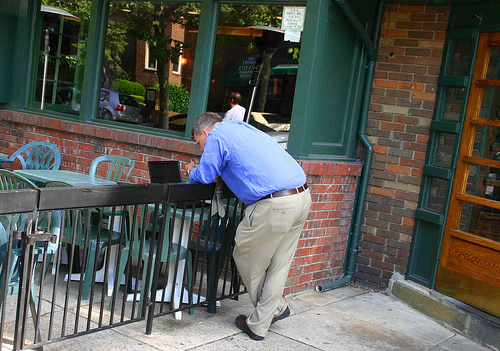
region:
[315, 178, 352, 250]
a brick wall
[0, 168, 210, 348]
a black wood fence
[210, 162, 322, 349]
a man wearing slacks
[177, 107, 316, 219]
a long sleeved blue shirt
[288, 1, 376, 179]
a green wall of the building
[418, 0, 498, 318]
a wooden door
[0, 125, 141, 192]
green chairs and table outside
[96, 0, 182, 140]
reflection in the glass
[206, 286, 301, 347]
brown shoes on a man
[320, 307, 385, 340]
cement on the ground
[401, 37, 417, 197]
brick exposed wall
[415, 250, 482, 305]
gold bottom portion of door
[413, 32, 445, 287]
green colored small window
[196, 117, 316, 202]
baby blue dress shirt on man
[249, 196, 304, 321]
tan khaki dress pants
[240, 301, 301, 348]
black dress shoes on man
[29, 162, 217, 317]
black metal bar fence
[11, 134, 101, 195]
different shades of green on furniture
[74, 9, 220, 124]
reflection of the street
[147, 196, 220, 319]
white bottom of table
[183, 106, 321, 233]
He has a blue shirt on.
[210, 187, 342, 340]
he is wearing tan pants.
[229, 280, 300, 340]
He has brown shoes.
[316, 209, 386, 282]
The building is brick.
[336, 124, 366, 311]
The gutter is green.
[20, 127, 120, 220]
The chairs are green.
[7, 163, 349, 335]
The fence is black.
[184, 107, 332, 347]
He is leaning.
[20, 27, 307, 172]
The windows are large.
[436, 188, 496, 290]
The door is wood.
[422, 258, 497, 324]
brass door kick-plate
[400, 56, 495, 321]
brick work and wood-frame entrance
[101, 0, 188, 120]
reflection in a window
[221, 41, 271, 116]
a man and a street sign reflected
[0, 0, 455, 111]
front window of a restaurant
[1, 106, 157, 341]
outdoor seating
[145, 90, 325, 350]
man at a cafe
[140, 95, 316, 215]
Bent over computer user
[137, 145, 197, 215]
lap top open on a table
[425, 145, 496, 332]
name inscribed in the wood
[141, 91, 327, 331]
man leaning over black railing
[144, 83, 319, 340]
man looking at a laptop screen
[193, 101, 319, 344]
man wearing khaki pants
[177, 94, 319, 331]
man wearing a long sleeved blue shirt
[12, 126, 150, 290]
green plastic patio tables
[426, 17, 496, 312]
wooden door with brass kickplate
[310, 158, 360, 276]
red brick wall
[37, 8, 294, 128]
windows in front of a restaurant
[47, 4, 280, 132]
reflection of a city street in a restaurant window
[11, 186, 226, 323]
black metal railing